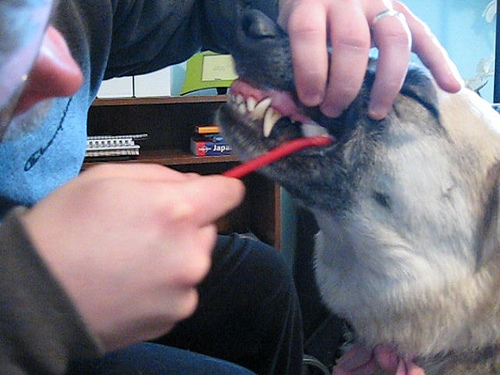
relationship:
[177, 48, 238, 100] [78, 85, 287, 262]
green frame on desk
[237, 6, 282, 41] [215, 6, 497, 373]
nose on dog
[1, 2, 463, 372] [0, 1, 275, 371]
person wearing sweatshirt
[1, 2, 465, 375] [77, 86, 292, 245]
person behind desk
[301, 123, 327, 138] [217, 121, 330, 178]
bristles on toothbrush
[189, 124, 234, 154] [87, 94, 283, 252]
stack in a bookcase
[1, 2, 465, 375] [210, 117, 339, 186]
person holding toothbrush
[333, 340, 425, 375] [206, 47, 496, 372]
bow on dog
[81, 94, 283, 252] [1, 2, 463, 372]
bookcase behind person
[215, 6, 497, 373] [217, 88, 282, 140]
dog has teeth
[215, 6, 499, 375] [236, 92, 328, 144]
dog has teeth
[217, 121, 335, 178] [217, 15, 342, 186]
toothbrush in mouth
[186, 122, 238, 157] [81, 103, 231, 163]
books on shelf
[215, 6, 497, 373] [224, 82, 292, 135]
dog has teeth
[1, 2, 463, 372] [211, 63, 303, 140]
person brushing dogs teeth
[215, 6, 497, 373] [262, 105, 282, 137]
dog showing tooth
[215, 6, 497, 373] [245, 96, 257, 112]
dog showing tooth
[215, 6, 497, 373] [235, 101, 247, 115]
dog showing tooth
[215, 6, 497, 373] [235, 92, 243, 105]
dog showing tooth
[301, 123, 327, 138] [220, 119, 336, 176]
bristles on toothbrush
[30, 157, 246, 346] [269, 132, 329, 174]
hand holding toothbrush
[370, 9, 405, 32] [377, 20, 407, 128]
ring in finger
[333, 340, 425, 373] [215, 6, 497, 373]
bow on dog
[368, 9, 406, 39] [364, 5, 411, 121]
ring on finger